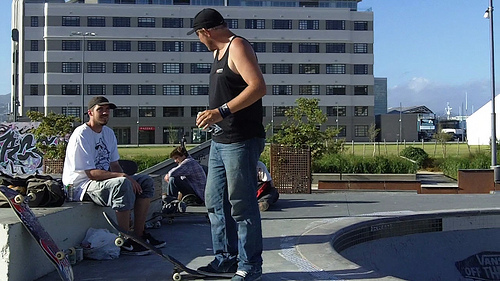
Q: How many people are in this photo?
A: Four.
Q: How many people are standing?
A: One.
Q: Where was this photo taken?
A: A skate park.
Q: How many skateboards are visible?
A: Two.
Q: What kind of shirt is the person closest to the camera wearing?
A: A black tank top.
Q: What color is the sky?
A: Blue.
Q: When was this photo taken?
A: Outside, during the daytime.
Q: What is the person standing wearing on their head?
A: A hat.